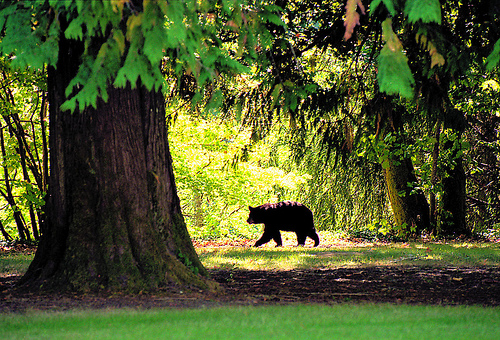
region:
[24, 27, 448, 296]
this is a nature setting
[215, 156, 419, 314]
this is a bear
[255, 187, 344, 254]
the bear is black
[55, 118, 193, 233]
this is a giant tree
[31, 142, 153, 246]
the tree bark is brown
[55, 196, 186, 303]
this bark is mossy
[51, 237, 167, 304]
this moss is green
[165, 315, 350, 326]
the grass here is very green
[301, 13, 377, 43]
some of the leaves are orange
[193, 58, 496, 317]
this is a forest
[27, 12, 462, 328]
A bear is walking in the woods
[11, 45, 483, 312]
A bear is walking close to a tree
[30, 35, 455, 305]
A bear is looking for food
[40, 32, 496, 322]
A bear is looking for a mate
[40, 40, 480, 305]
A bear is watching for danger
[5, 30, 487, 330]
A bear is hunting for small animals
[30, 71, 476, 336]
A bear has big sharp teeth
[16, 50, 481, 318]
The bear is up at daytime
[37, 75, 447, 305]
The bear is walking on the ground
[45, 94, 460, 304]
The bear is enjoying the day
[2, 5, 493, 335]
sun and shade in a park like setting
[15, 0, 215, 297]
large brown tree trunk near green grass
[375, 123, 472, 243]
two brown tree trunks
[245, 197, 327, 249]
bear walking in the woods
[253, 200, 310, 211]
sun and shade on a bear's back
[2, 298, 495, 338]
green grassy area near trees and a bear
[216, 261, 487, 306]
shaded area with dirt and leaves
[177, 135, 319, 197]
bright sunshine on green foliage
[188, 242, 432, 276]
sun and shaded area under the trees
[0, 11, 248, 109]
green foliage in a large tree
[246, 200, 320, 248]
Bear walking in woods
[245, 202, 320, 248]
Black bear in between large trees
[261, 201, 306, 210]
Sun shining on back of bear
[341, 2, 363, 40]
Dead branch attached to tree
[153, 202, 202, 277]
Plant growing on trunk of tree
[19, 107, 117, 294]
Large indentation in side of tree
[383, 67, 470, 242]
Two trees growing side by side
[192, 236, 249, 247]
Dead leaves on the ground next to bear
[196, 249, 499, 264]
Short green grass on the ground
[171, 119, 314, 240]
Small trees growing in the background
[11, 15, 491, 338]
The bear is casually walking around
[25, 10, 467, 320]
The bear is looking for food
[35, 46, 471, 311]
The bear is close to a big tree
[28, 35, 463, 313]
The bear is out in the open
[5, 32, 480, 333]
The bear has finished its hibernation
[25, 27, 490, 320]
The bear is looking for its mate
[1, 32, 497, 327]
The bear is hunting for animals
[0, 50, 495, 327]
The bear is a very big male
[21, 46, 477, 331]
The bear is out in the sunshine